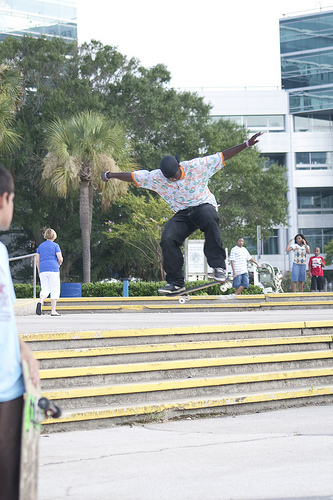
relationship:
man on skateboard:
[98, 128, 265, 296] [160, 276, 244, 305]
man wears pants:
[98, 128, 265, 296] [151, 202, 227, 275]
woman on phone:
[287, 230, 311, 298] [301, 237, 308, 251]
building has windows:
[256, 4, 329, 233] [234, 113, 292, 136]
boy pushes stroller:
[226, 229, 261, 292] [257, 261, 286, 300]